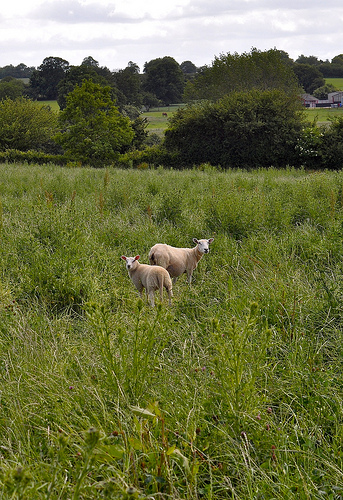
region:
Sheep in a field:
[93, 221, 222, 315]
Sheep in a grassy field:
[21, 179, 330, 495]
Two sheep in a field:
[112, 221, 223, 304]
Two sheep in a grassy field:
[17, 165, 324, 463]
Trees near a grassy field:
[9, 90, 330, 172]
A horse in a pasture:
[157, 107, 171, 118]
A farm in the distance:
[293, 84, 342, 108]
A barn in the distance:
[292, 83, 342, 115]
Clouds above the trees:
[8, 9, 331, 69]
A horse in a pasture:
[140, 101, 175, 125]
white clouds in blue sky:
[7, 8, 43, 31]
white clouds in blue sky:
[48, 10, 108, 43]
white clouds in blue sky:
[122, 10, 167, 36]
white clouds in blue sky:
[171, 16, 215, 49]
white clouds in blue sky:
[222, 4, 276, 36]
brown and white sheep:
[121, 254, 177, 308]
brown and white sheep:
[161, 230, 212, 266]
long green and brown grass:
[44, 335, 120, 406]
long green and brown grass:
[134, 321, 219, 397]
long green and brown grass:
[230, 327, 308, 434]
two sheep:
[107, 235, 228, 292]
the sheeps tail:
[158, 273, 170, 299]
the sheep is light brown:
[151, 240, 200, 270]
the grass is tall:
[13, 311, 305, 479]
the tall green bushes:
[64, 90, 127, 154]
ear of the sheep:
[131, 254, 140, 260]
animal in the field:
[153, 108, 174, 118]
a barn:
[303, 92, 341, 109]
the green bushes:
[5, 144, 52, 162]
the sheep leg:
[182, 271, 196, 289]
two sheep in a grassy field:
[120, 239, 209, 300]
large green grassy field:
[2, 160, 342, 499]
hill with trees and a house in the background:
[0, 76, 341, 172]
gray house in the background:
[291, 90, 341, 106]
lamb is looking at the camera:
[123, 254, 172, 299]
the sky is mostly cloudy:
[0, 1, 338, 69]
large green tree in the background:
[158, 97, 301, 165]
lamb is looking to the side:
[149, 237, 212, 285]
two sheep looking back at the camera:
[122, 237, 212, 303]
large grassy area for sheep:
[0, 170, 339, 496]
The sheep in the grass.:
[104, 231, 221, 307]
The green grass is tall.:
[76, 373, 255, 480]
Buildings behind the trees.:
[291, 81, 338, 116]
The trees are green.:
[80, 83, 336, 155]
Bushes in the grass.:
[67, 186, 291, 221]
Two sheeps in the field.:
[122, 225, 212, 304]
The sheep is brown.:
[112, 239, 180, 312]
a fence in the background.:
[131, 92, 205, 117]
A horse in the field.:
[154, 104, 176, 122]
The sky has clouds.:
[72, 1, 282, 53]